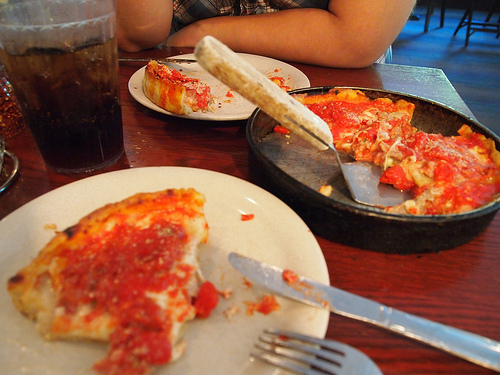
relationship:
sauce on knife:
[282, 270, 333, 312] [228, 251, 500, 373]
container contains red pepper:
[0, 77, 23, 140] [1, 78, 26, 141]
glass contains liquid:
[0, 0, 127, 174] [0, 34, 126, 175]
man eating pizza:
[112, 1, 418, 70] [142, 60, 216, 116]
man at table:
[112, 1, 418, 70] [0, 46, 499, 374]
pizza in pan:
[291, 87, 500, 216] [244, 85, 499, 254]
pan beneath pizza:
[244, 85, 499, 254] [291, 87, 500, 216]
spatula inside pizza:
[193, 35, 417, 208] [291, 87, 500, 216]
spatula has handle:
[193, 35, 417, 208] [193, 35, 334, 152]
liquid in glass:
[0, 34, 126, 175] [0, 0, 127, 174]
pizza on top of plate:
[142, 60, 216, 116] [128, 52, 311, 121]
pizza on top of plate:
[7, 187, 210, 365] [0, 165, 331, 374]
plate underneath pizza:
[128, 52, 311, 121] [142, 60, 216, 116]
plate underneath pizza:
[0, 165, 331, 374] [7, 187, 210, 365]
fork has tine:
[249, 326, 384, 374] [266, 326, 346, 355]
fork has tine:
[249, 326, 384, 374] [260, 336, 343, 363]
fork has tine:
[249, 326, 384, 374] [255, 342, 341, 373]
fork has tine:
[249, 326, 384, 374] [250, 352, 327, 374]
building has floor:
[8, 3, 498, 63] [391, 1, 499, 137]